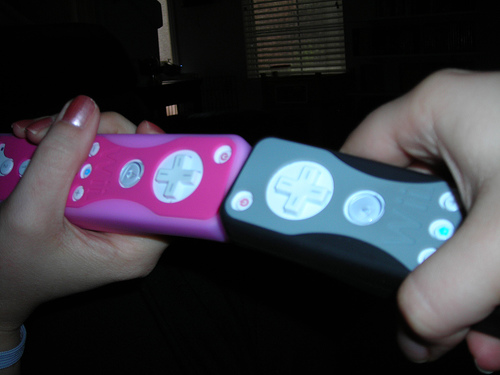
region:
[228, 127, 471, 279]
Game controller is blue.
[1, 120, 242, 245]
Game controller is pink.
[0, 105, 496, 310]
Two controllers are touching.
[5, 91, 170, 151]
The fingernails are painted.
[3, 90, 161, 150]
The fingernails are pink.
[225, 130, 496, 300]
Controller is two tone.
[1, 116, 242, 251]
Controller is two tone.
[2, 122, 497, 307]
Controllers have identical in functions.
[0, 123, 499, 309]
There are two controllers.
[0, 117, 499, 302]
Controllers match except in color.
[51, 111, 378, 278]
two wii controllers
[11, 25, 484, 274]
a man and a women with wii controllers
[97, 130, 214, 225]
a pink wii controller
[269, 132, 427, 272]
a grey and black wii controller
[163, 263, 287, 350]
black space in the photo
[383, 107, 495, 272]
the mans hands in the photo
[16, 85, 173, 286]
the womens hand in the photo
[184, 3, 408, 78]
the window in the back of the photo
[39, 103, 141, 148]
the womens painted finger nails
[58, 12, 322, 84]
the dark room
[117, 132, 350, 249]
two game controls touching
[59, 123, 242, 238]
pink game control in hand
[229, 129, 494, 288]
gray and black game control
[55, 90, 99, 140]
pink polish on nail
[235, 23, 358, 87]
open blinds on window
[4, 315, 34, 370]
white bracelet on wrist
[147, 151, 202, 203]
cross shaped button on control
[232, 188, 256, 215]
white button with red circle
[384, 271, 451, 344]
knuckle on man's thumb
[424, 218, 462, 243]
white and green button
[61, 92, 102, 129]
the fingernail of a person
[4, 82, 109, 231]
the thumb of a person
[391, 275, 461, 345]
the knuckle of a person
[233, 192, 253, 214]
a red and white power button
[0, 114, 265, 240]
a pink game controller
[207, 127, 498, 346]
a black game controller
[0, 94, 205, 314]
the hand of a person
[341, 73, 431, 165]
the finger of a person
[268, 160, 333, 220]
a white direction pad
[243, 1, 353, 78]
a window in the room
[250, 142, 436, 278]
a grey and black wii controller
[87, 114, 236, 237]
a light and dark pink wii controller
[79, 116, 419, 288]
two wii controllers touching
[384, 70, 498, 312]
a man's hand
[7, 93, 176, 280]
a woman's hand holding a controller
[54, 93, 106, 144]
metallic pink nail polish on a woman's thumb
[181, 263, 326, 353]
dark background behind two hand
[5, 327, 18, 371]
the white sleeve of a woman's shirt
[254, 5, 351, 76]
blinds on a window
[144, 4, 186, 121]
a light doorway